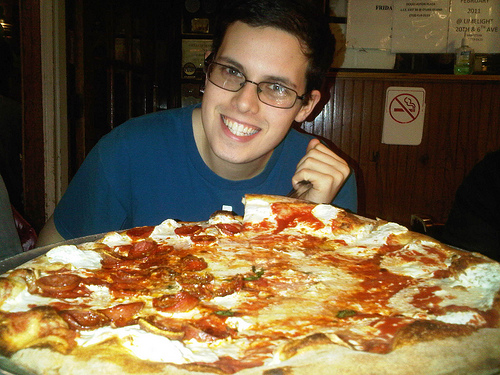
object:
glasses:
[199, 48, 312, 106]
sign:
[380, 78, 426, 153]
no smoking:
[387, 90, 425, 127]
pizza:
[0, 194, 500, 371]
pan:
[2, 210, 499, 372]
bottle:
[451, 30, 481, 77]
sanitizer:
[450, 28, 478, 81]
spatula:
[271, 175, 317, 213]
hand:
[285, 138, 361, 207]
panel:
[41, 3, 71, 246]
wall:
[312, 0, 500, 69]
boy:
[35, 0, 363, 253]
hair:
[203, 0, 337, 99]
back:
[348, 0, 494, 239]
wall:
[344, 70, 499, 242]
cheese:
[198, 225, 366, 336]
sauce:
[352, 248, 403, 322]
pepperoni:
[100, 245, 165, 289]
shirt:
[43, 118, 360, 248]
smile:
[213, 104, 267, 146]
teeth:
[218, 113, 273, 148]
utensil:
[290, 157, 318, 203]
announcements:
[332, 1, 500, 70]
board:
[326, 1, 497, 70]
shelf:
[288, 51, 500, 84]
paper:
[342, 0, 397, 56]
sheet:
[387, 2, 450, 53]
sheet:
[445, 0, 500, 55]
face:
[199, 18, 308, 166]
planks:
[360, 77, 373, 222]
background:
[0, 1, 498, 258]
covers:
[341, 1, 498, 69]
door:
[65, 0, 184, 183]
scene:
[9, 3, 495, 374]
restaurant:
[2, 3, 493, 342]